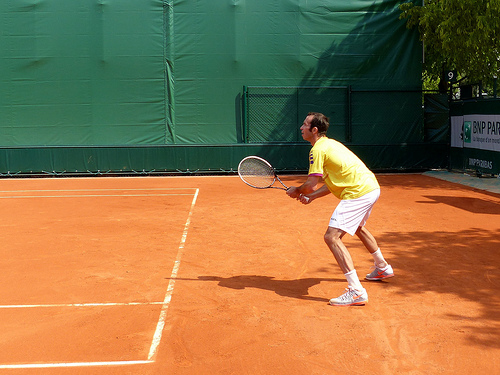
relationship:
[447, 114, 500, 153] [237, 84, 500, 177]
advertisement on fence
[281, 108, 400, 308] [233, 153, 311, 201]
man holding racket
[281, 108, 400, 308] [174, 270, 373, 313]
man has shadow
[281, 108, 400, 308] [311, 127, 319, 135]
man has ear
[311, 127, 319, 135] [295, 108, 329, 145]
ear on head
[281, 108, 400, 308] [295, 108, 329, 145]
man has head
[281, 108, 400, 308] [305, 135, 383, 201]
man in shirt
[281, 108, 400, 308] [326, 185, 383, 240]
man in shorts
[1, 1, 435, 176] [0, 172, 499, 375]
covering on court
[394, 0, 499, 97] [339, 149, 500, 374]
trees on back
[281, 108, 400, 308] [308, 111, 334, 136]
man has hair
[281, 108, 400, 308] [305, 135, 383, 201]
man has shirt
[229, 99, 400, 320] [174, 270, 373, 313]
player has shadow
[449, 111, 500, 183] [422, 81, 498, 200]
signs on walls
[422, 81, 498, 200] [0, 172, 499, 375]
walls on court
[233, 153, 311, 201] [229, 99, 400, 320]
racket held by player